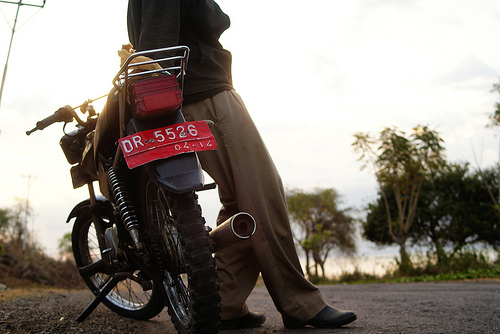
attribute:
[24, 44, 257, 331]
motorcycle — parked, leaning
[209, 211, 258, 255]
exhast — silver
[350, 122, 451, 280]
tree — green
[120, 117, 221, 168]
license plate — red, white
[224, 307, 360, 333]
shoes — paired black, black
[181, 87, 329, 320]
pants — brown, tanned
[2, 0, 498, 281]
sky — bright, white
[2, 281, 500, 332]
road — black, gravel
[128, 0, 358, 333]
person — waiting, leaning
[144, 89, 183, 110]
light — red